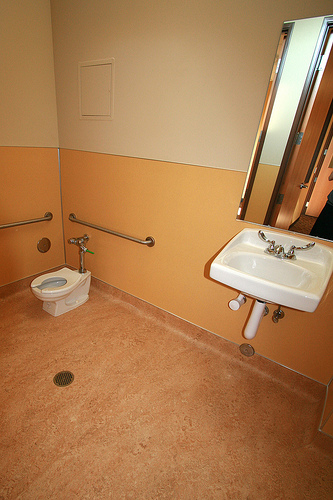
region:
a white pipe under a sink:
[241, 297, 272, 345]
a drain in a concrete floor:
[49, 365, 83, 395]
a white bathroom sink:
[196, 219, 331, 309]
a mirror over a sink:
[223, 14, 331, 238]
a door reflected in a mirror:
[268, 30, 314, 229]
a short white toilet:
[30, 233, 95, 319]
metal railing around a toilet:
[63, 210, 158, 255]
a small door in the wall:
[72, 50, 117, 128]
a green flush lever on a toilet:
[80, 243, 97, 257]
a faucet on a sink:
[256, 231, 303, 256]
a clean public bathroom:
[27, 157, 326, 480]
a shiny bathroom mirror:
[234, 11, 321, 228]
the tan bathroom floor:
[144, 414, 267, 487]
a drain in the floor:
[47, 367, 82, 390]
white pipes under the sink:
[226, 296, 267, 342]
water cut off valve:
[269, 312, 284, 330]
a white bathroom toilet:
[29, 259, 100, 317]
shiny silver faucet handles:
[254, 224, 322, 263]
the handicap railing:
[59, 205, 156, 251]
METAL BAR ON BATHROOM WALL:
[58, 202, 179, 252]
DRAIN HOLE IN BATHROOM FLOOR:
[34, 352, 126, 414]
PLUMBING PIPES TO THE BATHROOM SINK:
[219, 288, 294, 368]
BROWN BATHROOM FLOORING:
[27, 298, 67, 327]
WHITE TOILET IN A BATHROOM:
[17, 240, 130, 320]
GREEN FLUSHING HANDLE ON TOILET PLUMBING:
[62, 227, 100, 264]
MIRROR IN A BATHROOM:
[238, 145, 327, 269]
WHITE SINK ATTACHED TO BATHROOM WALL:
[222, 220, 331, 349]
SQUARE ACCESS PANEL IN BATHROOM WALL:
[56, 41, 136, 133]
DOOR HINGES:
[272, 121, 311, 231]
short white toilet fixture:
[28, 261, 97, 321]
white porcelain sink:
[202, 221, 331, 321]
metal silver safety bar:
[62, 207, 162, 249]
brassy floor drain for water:
[40, 364, 88, 396]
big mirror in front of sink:
[227, 8, 331, 240]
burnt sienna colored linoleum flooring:
[0, 260, 331, 498]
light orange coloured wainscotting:
[0, 143, 329, 385]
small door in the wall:
[68, 56, 128, 128]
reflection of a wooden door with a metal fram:
[268, 15, 332, 232]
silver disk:
[35, 235, 60, 258]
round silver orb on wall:
[26, 231, 58, 255]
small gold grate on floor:
[42, 368, 79, 387]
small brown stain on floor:
[123, 437, 171, 450]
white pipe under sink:
[239, 300, 267, 346]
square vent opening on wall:
[53, 46, 138, 137]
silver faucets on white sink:
[246, 227, 319, 262]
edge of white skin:
[241, 251, 307, 285]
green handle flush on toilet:
[80, 245, 101, 255]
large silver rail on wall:
[64, 206, 157, 245]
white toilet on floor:
[32, 265, 111, 317]